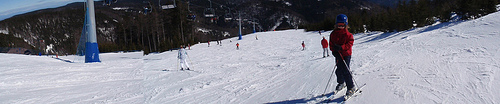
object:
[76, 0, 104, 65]
pole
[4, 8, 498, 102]
snow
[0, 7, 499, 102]
ground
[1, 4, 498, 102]
photo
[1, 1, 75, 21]
sky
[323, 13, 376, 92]
boy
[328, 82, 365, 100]
ski skates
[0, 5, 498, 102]
weather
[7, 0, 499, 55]
trees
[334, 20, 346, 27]
sunglasses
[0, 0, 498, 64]
mountains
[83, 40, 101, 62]
blue trim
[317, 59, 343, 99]
ski pole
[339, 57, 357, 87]
ski pole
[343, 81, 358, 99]
boot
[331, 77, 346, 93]
boot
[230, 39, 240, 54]
person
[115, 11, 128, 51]
tree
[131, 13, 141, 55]
tree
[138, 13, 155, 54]
tree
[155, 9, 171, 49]
tree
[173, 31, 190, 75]
person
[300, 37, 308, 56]
person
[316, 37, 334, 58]
person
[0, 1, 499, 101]
ski resort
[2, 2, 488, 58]
background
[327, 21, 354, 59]
jacket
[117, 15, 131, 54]
tree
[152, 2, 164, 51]
tree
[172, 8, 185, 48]
tree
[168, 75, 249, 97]
track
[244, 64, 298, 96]
track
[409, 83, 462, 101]
track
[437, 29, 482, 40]
track